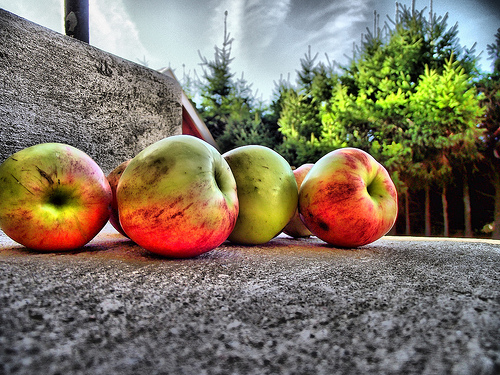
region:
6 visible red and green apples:
[1, 133, 398, 258]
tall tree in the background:
[447, 79, 479, 238]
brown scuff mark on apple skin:
[34, 161, 55, 188]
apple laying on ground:
[116, 133, 241, 259]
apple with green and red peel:
[299, 146, 398, 253]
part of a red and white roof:
[158, 63, 226, 155]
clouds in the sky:
[258, 6, 338, 58]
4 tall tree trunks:
[399, 171, 474, 236]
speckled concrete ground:
[260, 253, 436, 348]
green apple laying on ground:
[217, 146, 298, 245]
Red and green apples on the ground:
[8, 103, 417, 280]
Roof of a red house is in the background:
[153, 61, 241, 143]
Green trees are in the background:
[205, 13, 499, 167]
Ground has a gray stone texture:
[31, 251, 450, 372]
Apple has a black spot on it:
[301, 202, 339, 239]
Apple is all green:
[225, 138, 301, 240]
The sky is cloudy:
[106, 0, 473, 60]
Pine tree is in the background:
[196, 7, 259, 123]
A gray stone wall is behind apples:
[6, 33, 185, 150]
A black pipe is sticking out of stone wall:
[55, 5, 97, 47]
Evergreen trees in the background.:
[147, 65, 272, 176]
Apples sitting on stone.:
[6, 144, 497, 261]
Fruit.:
[61, 130, 346, 227]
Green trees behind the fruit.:
[260, 74, 437, 216]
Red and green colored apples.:
[82, 54, 323, 306]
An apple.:
[103, 134, 261, 269]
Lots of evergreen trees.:
[299, 65, 441, 174]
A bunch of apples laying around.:
[25, 110, 485, 283]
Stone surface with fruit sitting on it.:
[43, 92, 315, 365]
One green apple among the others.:
[224, 128, 301, 235]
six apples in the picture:
[13, 108, 488, 303]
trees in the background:
[333, 26, 497, 197]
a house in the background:
[148, 43, 253, 225]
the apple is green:
[237, 140, 284, 200]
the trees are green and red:
[371, 56, 443, 189]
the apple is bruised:
[6, 141, 47, 216]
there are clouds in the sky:
[229, 6, 415, 77]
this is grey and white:
[251, 295, 391, 363]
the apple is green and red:
[98, 123, 248, 263]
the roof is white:
[131, 52, 313, 156]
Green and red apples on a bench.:
[2, 134, 398, 257]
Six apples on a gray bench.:
[1, 135, 398, 258]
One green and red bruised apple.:
[115, 132, 237, 254]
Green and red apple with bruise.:
[298, 145, 398, 247]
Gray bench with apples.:
[2, 35, 499, 373]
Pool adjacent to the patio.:
[59, 1, 103, 43]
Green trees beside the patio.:
[391, 0, 497, 237]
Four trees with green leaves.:
[399, 0, 496, 237]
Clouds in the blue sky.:
[102, 3, 497, 62]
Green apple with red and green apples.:
[237, 125, 296, 244]